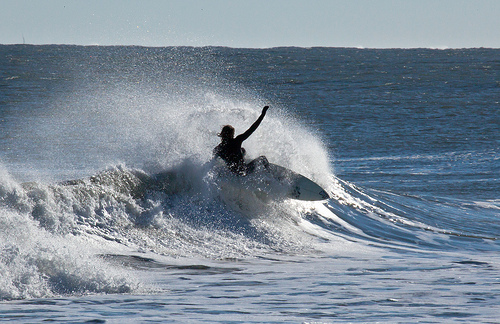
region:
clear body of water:
[360, 85, 402, 120]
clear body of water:
[403, 113, 441, 144]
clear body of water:
[343, 122, 390, 162]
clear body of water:
[434, 98, 470, 128]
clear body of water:
[442, 65, 482, 92]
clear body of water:
[363, 56, 408, 84]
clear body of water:
[293, 58, 314, 78]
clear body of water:
[32, 54, 56, 79]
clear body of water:
[17, 82, 42, 114]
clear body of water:
[300, 62, 317, 75]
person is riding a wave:
[166, 115, 316, 205]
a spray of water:
[23, 48, 133, 140]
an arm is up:
[223, 107, 256, 149]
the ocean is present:
[326, 79, 441, 164]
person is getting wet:
[202, 102, 265, 162]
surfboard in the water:
[248, 163, 340, 215]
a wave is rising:
[71, 162, 370, 220]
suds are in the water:
[209, 282, 347, 312]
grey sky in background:
[86, 6, 343, 32]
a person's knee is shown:
[245, 148, 279, 165]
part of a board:
[325, 191, 327, 193]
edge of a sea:
[283, 228, 290, 237]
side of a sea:
[303, 266, 313, 276]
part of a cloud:
[426, 95, 427, 101]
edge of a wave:
[302, 226, 314, 246]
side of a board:
[317, 122, 321, 142]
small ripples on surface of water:
[355, 60, 497, 141]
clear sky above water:
[5, 0, 486, 45]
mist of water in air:
[95, 42, 184, 148]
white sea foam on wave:
[18, 237, 96, 295]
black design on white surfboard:
[288, 184, 304, 198]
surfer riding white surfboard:
[110, 67, 370, 264]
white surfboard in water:
[265, 157, 339, 216]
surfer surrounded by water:
[144, 81, 381, 275]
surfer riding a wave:
[18, 65, 390, 281]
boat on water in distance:
[10, 28, 45, 52]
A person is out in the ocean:
[15, 21, 480, 306]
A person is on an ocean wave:
[20, 10, 480, 305]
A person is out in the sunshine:
[31, 25, 461, 305]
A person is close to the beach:
[45, 30, 435, 310]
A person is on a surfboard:
[43, 30, 458, 290]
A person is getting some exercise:
[20, 25, 461, 306]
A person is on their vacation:
[35, 25, 470, 300]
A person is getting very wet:
[33, 35, 464, 305]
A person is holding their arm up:
[26, 25, 436, 285]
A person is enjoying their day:
[30, 33, 458, 295]